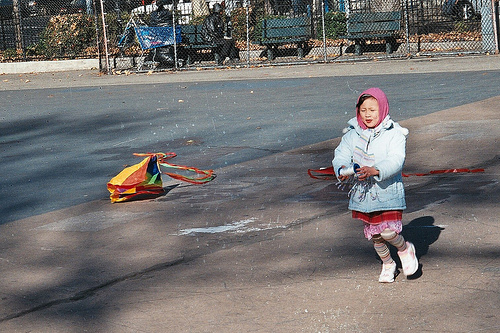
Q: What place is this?
A: It is a park.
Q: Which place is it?
A: It is a park.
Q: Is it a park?
A: Yes, it is a park.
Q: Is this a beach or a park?
A: It is a park.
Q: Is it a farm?
A: No, it is a park.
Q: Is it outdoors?
A: Yes, it is outdoors.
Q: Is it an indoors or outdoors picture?
A: It is outdoors.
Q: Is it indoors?
A: No, it is outdoors.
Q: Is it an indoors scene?
A: No, it is outdoors.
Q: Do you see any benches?
A: Yes, there is a bench.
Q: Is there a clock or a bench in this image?
A: Yes, there is a bench.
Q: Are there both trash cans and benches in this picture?
A: No, there is a bench but no trash cans.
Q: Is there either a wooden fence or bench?
A: Yes, there is a wood bench.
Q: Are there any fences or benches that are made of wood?
A: Yes, the bench is made of wood.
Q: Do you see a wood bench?
A: Yes, there is a wood bench.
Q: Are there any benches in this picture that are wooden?
A: Yes, there is a bench that is wooden.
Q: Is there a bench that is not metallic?
A: Yes, there is a wooden bench.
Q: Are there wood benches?
A: Yes, there is a bench that is made of wood.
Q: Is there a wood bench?
A: Yes, there is a bench that is made of wood.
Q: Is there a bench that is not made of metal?
A: Yes, there is a bench that is made of wood.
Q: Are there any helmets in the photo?
A: No, there are no helmets.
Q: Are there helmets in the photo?
A: No, there are no helmets.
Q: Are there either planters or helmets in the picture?
A: No, there are no helmets or planters.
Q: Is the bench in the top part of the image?
A: Yes, the bench is in the top of the image.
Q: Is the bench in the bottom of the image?
A: No, the bench is in the top of the image.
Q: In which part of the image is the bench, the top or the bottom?
A: The bench is in the top of the image.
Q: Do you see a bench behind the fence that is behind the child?
A: Yes, there is a bench behind the fence.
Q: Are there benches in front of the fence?
A: No, the bench is behind the fence.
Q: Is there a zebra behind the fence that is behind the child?
A: No, there is a bench behind the fence.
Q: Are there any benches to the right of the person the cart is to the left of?
A: Yes, there is a bench to the right of the person.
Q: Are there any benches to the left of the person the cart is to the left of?
A: No, the bench is to the right of the person.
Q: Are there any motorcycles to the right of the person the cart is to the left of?
A: No, there is a bench to the right of the person.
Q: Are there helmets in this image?
A: No, there are no helmets.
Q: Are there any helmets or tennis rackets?
A: No, there are no helmets or tennis rackets.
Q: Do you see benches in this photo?
A: Yes, there is a bench.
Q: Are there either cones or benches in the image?
A: Yes, there is a bench.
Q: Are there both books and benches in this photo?
A: No, there is a bench but no books.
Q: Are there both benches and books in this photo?
A: No, there is a bench but no books.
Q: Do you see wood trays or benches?
A: Yes, there is a wood bench.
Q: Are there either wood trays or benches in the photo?
A: Yes, there is a wood bench.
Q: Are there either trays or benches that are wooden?
A: Yes, the bench is wooden.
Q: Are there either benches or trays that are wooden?
A: Yes, the bench is wooden.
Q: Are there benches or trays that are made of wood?
A: Yes, the bench is made of wood.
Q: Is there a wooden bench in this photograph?
A: Yes, there is a wood bench.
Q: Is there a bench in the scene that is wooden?
A: Yes, there is a bench that is wooden.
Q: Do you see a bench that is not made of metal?
A: Yes, there is a bench that is made of wood.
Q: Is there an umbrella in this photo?
A: No, there are no umbrellas.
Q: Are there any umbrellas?
A: No, there are no umbrellas.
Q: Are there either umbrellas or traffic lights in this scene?
A: No, there are no umbrellas or traffic lights.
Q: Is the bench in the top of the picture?
A: Yes, the bench is in the top of the image.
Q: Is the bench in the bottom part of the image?
A: No, the bench is in the top of the image.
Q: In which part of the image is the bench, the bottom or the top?
A: The bench is in the top of the image.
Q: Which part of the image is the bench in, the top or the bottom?
A: The bench is in the top of the image.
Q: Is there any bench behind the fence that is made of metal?
A: Yes, there is a bench behind the fence.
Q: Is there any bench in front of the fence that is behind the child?
A: No, the bench is behind the fence.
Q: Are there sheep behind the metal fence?
A: No, there is a bench behind the fence.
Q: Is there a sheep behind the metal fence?
A: No, there is a bench behind the fence.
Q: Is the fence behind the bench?
A: No, the bench is behind the fence.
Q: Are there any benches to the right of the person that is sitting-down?
A: Yes, there is a bench to the right of the person.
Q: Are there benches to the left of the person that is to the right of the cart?
A: No, the bench is to the right of the person.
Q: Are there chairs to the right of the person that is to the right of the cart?
A: No, there is a bench to the right of the person.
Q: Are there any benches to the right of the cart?
A: Yes, there is a bench to the right of the cart.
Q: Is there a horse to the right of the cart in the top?
A: No, there is a bench to the right of the cart.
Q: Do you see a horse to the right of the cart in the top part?
A: No, there is a bench to the right of the cart.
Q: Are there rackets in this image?
A: No, there are no rackets.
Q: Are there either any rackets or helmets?
A: No, there are no rackets or helmets.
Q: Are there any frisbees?
A: No, there are no frisbees.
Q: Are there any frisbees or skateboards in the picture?
A: No, there are no frisbees or skateboards.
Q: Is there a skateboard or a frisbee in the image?
A: No, there are no frisbees or skateboards.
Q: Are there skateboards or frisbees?
A: No, there are no frisbees or skateboards.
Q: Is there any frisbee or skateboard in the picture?
A: No, there are no frisbees or skateboards.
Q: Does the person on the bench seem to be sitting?
A: Yes, the person is sitting.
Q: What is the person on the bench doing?
A: The person is sitting.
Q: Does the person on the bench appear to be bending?
A: No, the person is sitting.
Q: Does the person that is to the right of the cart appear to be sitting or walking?
A: The person is sitting.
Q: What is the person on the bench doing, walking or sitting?
A: The person is sitting.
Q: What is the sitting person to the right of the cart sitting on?
A: The person is sitting on the bench.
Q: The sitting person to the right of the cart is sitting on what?
A: The person is sitting on the bench.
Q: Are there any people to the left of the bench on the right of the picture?
A: Yes, there is a person to the left of the bench.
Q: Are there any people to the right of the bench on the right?
A: No, the person is to the left of the bench.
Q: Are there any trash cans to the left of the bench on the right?
A: No, there is a person to the left of the bench.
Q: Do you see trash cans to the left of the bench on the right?
A: No, there is a person to the left of the bench.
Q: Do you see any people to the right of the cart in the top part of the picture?
A: Yes, there is a person to the right of the cart.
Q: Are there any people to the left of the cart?
A: No, the person is to the right of the cart.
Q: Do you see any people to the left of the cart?
A: No, the person is to the right of the cart.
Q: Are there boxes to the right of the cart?
A: No, there is a person to the right of the cart.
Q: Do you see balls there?
A: No, there are no balls.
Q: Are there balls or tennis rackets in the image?
A: No, there are no balls or tennis rackets.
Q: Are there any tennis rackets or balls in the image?
A: No, there are no balls or tennis rackets.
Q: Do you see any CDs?
A: No, there are no cds.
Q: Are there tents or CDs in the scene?
A: No, there are no CDs or tents.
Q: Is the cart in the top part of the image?
A: Yes, the cart is in the top of the image.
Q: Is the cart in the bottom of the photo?
A: No, the cart is in the top of the image.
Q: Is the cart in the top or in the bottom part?
A: The cart is in the top of the image.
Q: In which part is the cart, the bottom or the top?
A: The cart is in the top of the image.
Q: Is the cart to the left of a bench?
A: Yes, the cart is to the left of a bench.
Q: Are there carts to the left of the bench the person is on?
A: Yes, there is a cart to the left of the bench.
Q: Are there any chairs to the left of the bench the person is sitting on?
A: No, there is a cart to the left of the bench.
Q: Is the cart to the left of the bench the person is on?
A: Yes, the cart is to the left of the bench.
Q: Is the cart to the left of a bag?
A: No, the cart is to the left of the bench.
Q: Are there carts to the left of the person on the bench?
A: Yes, there is a cart to the left of the person.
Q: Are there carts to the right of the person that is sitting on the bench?
A: No, the cart is to the left of the person.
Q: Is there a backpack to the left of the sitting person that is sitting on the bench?
A: No, there is a cart to the left of the person.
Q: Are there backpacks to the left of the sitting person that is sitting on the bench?
A: No, there is a cart to the left of the person.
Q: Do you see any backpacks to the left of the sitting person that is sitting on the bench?
A: No, there is a cart to the left of the person.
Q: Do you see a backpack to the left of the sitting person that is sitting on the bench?
A: No, there is a cart to the left of the person.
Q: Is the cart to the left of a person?
A: Yes, the cart is to the left of a person.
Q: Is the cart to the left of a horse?
A: No, the cart is to the left of a person.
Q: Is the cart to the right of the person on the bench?
A: No, the cart is to the left of the person.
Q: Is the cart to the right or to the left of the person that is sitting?
A: The cart is to the left of the person.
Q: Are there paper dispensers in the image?
A: No, there are no paper dispensers.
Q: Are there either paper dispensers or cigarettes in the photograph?
A: No, there are no paper dispensers or cigarettes.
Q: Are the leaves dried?
A: Yes, the leaves are dried.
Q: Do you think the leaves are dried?
A: Yes, the leaves are dried.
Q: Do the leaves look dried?
A: Yes, the leaves are dried.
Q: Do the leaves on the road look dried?
A: Yes, the leaves are dried.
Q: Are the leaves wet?
A: No, the leaves are dried.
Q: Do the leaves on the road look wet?
A: No, the leaves are dried.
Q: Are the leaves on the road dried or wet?
A: The leaves are dried.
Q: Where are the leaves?
A: The leaves are on the road.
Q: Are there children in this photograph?
A: Yes, there is a child.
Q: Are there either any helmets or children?
A: Yes, there is a child.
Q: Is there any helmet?
A: No, there are no helmets.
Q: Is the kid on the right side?
A: Yes, the kid is on the right of the image.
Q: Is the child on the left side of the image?
A: No, the child is on the right of the image.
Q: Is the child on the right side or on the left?
A: The child is on the right of the image.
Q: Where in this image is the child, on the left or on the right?
A: The child is on the right of the image.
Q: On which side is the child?
A: The child is on the right of the image.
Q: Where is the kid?
A: The kid is on the road.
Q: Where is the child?
A: The kid is on the road.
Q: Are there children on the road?
A: Yes, there is a child on the road.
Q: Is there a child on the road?
A: Yes, there is a child on the road.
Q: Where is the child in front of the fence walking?
A: The kid is walking on the road.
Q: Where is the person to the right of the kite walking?
A: The kid is walking on the road.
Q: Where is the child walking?
A: The kid is walking on the road.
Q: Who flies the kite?
A: The kid flies the kite.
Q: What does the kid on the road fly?
A: The kid flies the kite.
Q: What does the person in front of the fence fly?
A: The kid flies the kite.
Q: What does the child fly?
A: The kid flies the kite.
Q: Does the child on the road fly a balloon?
A: No, the child flies the kite.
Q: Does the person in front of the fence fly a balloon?
A: No, the child flies the kite.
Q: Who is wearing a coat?
A: The child is wearing a coat.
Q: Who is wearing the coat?
A: The child is wearing a coat.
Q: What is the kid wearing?
A: The kid is wearing a coat.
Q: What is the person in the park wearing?
A: The kid is wearing a coat.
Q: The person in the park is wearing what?
A: The kid is wearing a coat.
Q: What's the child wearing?
A: The kid is wearing a coat.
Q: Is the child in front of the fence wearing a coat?
A: Yes, the child is wearing a coat.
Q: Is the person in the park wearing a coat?
A: Yes, the child is wearing a coat.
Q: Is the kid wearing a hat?
A: No, the kid is wearing a coat.